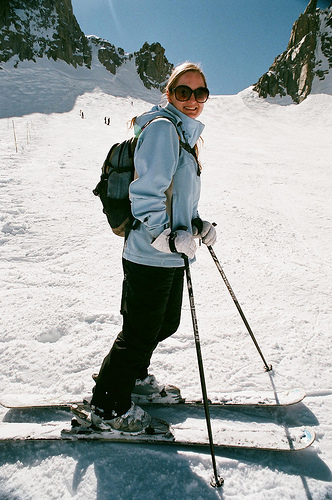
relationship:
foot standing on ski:
[91, 403, 170, 434] [1, 422, 315, 451]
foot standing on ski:
[132, 375, 182, 401] [0, 391, 306, 410]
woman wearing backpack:
[92, 62, 217, 436] [94, 137, 137, 237]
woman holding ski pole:
[92, 62, 217, 436] [169, 226, 224, 488]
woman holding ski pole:
[92, 62, 217, 436] [192, 217, 274, 373]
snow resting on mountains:
[1, 68, 330, 498] [0, 0, 331, 104]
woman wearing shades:
[92, 62, 217, 436] [171, 85, 210, 104]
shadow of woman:
[73, 441, 220, 499] [92, 62, 217, 436]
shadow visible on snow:
[73, 441, 220, 499] [1, 68, 330, 498]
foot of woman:
[91, 403, 170, 434] [92, 62, 217, 436]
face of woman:
[171, 71, 207, 118] [92, 62, 217, 436]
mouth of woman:
[184, 105, 199, 113] [92, 62, 217, 436]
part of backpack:
[100, 197, 132, 237] [94, 137, 137, 237]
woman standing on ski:
[92, 62, 217, 436] [1, 422, 315, 451]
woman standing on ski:
[92, 62, 217, 436] [0, 391, 306, 410]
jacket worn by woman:
[122, 102, 205, 269] [92, 62, 217, 436]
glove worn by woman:
[151, 227, 199, 259] [92, 62, 217, 436]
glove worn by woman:
[201, 221, 218, 247] [92, 62, 217, 436]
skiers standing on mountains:
[78, 110, 85, 120] [0, 0, 331, 104]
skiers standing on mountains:
[104, 116, 112, 125] [0, 0, 331, 104]